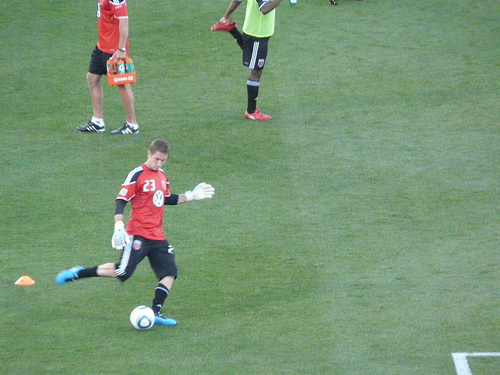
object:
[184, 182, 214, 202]
gloves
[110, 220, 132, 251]
gloves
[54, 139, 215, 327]
man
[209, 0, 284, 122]
man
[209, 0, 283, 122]
man stretching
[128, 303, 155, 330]
ball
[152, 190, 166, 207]
logo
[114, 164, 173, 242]
shirt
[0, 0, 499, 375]
field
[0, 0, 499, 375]
grass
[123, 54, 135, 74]
beverages